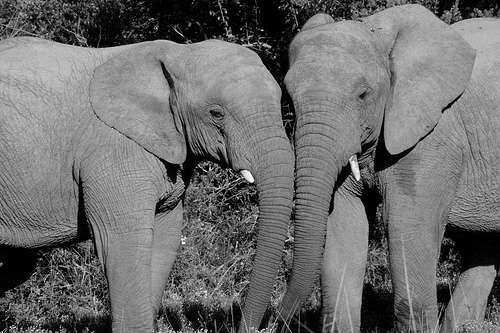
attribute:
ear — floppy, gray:
[90, 57, 176, 157]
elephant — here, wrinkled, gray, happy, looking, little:
[3, 68, 259, 316]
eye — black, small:
[201, 107, 230, 120]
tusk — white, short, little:
[238, 168, 261, 185]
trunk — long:
[237, 132, 287, 325]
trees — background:
[106, 2, 159, 25]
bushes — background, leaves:
[169, 220, 219, 268]